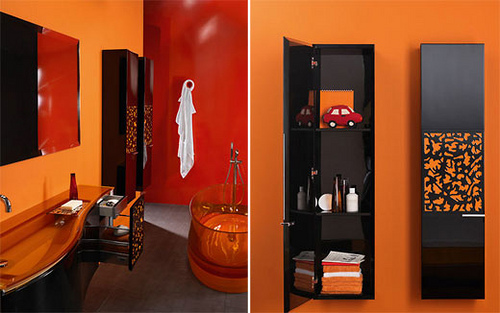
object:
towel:
[175, 81, 197, 179]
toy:
[322, 104, 364, 129]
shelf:
[314, 127, 371, 132]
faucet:
[0, 194, 12, 213]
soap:
[62, 199, 84, 211]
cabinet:
[281, 35, 376, 312]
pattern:
[423, 131, 484, 212]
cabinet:
[419, 42, 485, 300]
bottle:
[68, 172, 78, 202]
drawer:
[97, 194, 129, 220]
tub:
[187, 182, 248, 294]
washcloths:
[321, 266, 364, 295]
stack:
[321, 262, 363, 295]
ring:
[184, 79, 195, 90]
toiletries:
[317, 176, 360, 212]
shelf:
[311, 212, 370, 216]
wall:
[251, 0, 500, 313]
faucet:
[224, 142, 245, 206]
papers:
[291, 249, 314, 263]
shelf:
[315, 294, 375, 300]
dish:
[48, 201, 90, 216]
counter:
[1, 184, 115, 294]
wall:
[143, 1, 248, 212]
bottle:
[346, 187, 359, 212]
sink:
[1, 195, 93, 279]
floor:
[69, 202, 246, 312]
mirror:
[34, 22, 82, 156]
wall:
[0, 0, 102, 187]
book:
[321, 261, 361, 267]